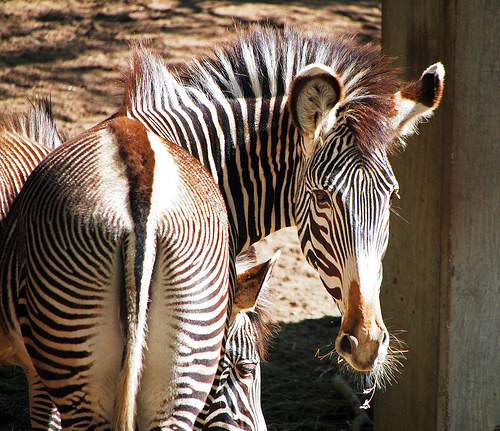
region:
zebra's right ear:
[278, 59, 348, 149]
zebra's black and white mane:
[221, 19, 389, 94]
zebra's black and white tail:
[108, 227, 180, 427]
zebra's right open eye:
[311, 176, 355, 224]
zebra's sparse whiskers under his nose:
[318, 339, 425, 396]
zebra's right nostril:
[333, 315, 364, 372]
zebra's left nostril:
[371, 326, 418, 370]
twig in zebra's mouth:
[356, 362, 413, 426]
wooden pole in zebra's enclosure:
[427, 131, 487, 388]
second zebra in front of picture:
[201, 281, 264, 429]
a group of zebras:
[4, 22, 456, 416]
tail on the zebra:
[98, 201, 173, 407]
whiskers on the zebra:
[325, 310, 411, 390]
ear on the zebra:
[235, 265, 270, 317]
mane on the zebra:
[215, 25, 375, 71]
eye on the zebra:
[241, 350, 267, 390]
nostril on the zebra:
[326, 315, 368, 357]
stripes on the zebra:
[195, 100, 298, 198]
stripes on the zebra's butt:
[24, 228, 87, 323]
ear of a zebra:
[382, 48, 455, 142]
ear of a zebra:
[281, 55, 346, 157]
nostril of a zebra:
[371, 325, 388, 358]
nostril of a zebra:
[336, 328, 364, 361]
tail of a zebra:
[98, 233, 174, 430]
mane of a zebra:
[115, 14, 425, 149]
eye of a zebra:
[306, 181, 338, 214]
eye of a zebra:
[382, 181, 399, 211]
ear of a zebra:
[228, 246, 288, 313]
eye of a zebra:
[231, 356, 258, 379]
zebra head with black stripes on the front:
[260, 62, 446, 428]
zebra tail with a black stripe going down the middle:
[93, 223, 192, 422]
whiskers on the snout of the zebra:
[299, 309, 452, 399]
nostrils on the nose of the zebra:
[313, 310, 417, 385]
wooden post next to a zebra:
[371, 9, 496, 415]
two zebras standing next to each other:
[9, 14, 471, 418]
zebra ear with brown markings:
[219, 249, 296, 336]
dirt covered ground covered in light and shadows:
[0, 12, 327, 129]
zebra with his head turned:
[29, 55, 443, 424]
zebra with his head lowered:
[117, 272, 317, 429]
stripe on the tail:
[106, 114, 164, 326]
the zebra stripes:
[117, 234, 141, 429]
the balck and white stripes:
[27, 137, 100, 396]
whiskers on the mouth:
[387, 312, 412, 394]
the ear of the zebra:
[225, 255, 287, 325]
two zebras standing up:
[42, 25, 450, 428]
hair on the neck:
[122, 17, 397, 125]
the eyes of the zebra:
[312, 179, 397, 211]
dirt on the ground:
[41, 6, 116, 94]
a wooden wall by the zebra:
[450, 0, 493, 429]